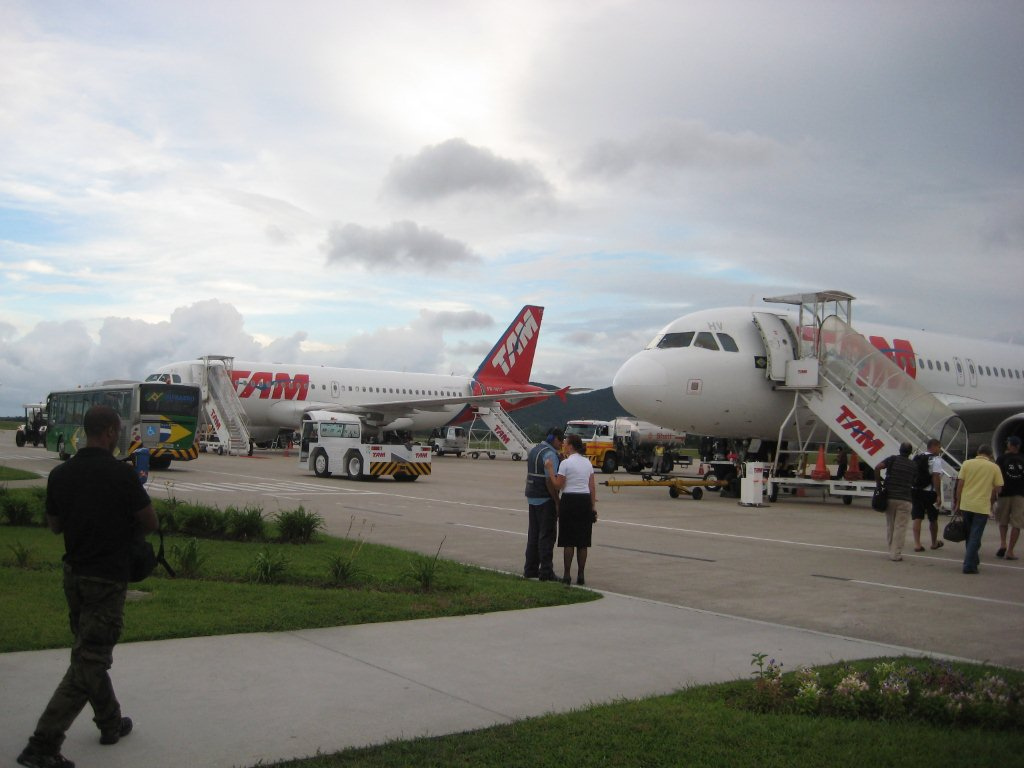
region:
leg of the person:
[87, 669, 113, 698]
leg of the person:
[46, 683, 104, 728]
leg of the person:
[555, 556, 574, 566]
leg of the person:
[539, 538, 555, 564]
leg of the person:
[531, 546, 548, 562]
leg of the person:
[885, 518, 899, 557]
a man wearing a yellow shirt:
[948, 460, 1005, 509]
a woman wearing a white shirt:
[554, 462, 596, 495]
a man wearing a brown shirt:
[874, 458, 917, 498]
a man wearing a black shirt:
[52, 453, 145, 556]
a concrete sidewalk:
[143, 589, 767, 751]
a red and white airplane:
[153, 323, 552, 445]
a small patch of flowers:
[735, 649, 1020, 735]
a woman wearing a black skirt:
[557, 493, 602, 554]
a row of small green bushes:
[178, 497, 324, 546]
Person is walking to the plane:
[20, 404, 161, 766]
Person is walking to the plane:
[557, 428, 602, 583]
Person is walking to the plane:
[514, 424, 565, 577]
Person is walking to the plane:
[866, 437, 915, 551]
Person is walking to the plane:
[909, 430, 945, 547]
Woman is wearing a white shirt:
[558, 448, 594, 497]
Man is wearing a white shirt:
[912, 449, 942, 491]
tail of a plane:
[481, 290, 558, 402]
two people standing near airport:
[520, 426, 601, 599]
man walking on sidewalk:
[17, 394, 167, 766]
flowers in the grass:
[726, 644, 1022, 743]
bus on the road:
[29, 380, 223, 475]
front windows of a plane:
[650, 318, 745, 367]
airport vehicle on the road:
[291, 396, 447, 500]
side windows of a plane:
[298, 373, 466, 410]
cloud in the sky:
[383, 137, 544, 210]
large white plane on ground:
[160, 287, 616, 456]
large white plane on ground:
[621, 274, 1015, 489]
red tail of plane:
[479, 288, 547, 391]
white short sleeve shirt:
[561, 454, 597, 493]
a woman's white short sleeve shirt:
[551, 449, 594, 498]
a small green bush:
[270, 505, 351, 531]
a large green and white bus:
[38, 379, 198, 463]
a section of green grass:
[261, 650, 1021, 767]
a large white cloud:
[378, 135, 549, 211]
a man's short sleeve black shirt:
[38, 448, 157, 569]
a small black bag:
[940, 514, 973, 547]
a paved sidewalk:
[7, 575, 903, 765]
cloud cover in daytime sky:
[4, 2, 1019, 405]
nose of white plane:
[615, 302, 1021, 480]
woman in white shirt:
[550, 432, 601, 585]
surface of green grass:
[283, 654, 1018, 765]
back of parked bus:
[46, 387, 202, 465]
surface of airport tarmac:
[2, 435, 1018, 660]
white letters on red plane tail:
[485, 303, 550, 377]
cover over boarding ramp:
[803, 317, 988, 474]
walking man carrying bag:
[21, 400, 162, 765]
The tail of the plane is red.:
[442, 314, 550, 388]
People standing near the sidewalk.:
[517, 421, 593, 598]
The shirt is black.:
[53, 452, 130, 558]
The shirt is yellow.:
[953, 456, 1007, 517]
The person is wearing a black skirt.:
[556, 481, 598, 554]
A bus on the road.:
[29, 374, 220, 473]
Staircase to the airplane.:
[802, 316, 964, 469]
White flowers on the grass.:
[778, 647, 1000, 725]